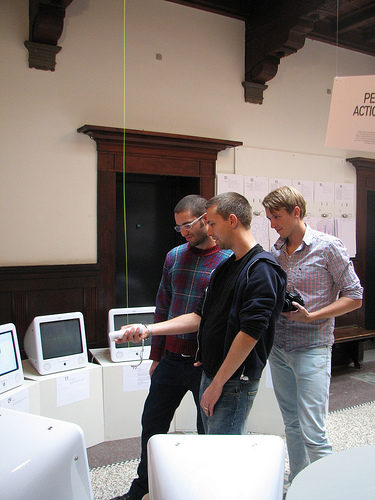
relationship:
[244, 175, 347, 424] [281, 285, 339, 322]
man held camera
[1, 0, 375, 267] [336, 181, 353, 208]
wall behind papers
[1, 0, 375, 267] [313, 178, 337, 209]
wall behind papers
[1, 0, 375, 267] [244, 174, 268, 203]
wall behind papers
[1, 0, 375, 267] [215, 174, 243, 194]
wall behind papers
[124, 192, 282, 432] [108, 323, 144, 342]
man held game controller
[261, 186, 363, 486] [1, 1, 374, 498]
man in a room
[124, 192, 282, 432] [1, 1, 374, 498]
man in a room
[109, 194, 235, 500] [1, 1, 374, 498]
man in a room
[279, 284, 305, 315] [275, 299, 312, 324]
camera in hand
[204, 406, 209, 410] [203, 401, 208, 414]
ring on finger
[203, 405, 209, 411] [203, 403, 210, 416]
ring on mans finger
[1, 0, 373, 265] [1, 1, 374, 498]
wall painted of room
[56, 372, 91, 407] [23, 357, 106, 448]
paper on box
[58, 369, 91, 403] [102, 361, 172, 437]
paper on box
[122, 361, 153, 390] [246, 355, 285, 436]
paper on box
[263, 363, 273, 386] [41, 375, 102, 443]
paper on box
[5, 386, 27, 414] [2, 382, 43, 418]
paper on box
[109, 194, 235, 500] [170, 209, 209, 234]
man wearing glasses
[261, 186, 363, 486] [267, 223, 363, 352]
man wearing a button-up shirt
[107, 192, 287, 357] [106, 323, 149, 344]
man holding game controller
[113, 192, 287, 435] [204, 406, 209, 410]
man wearing a ring